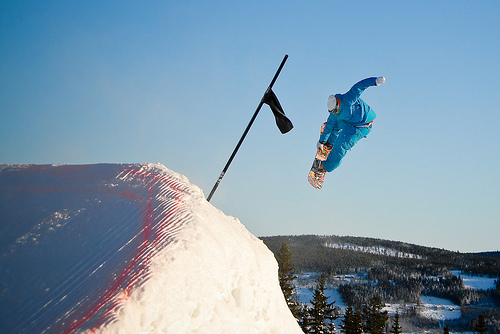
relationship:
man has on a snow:
[303, 70, 385, 189] [197, 226, 223, 253]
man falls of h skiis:
[303, 70, 385, 189] [192, 55, 300, 200]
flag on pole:
[262, 87, 298, 137] [202, 29, 294, 226]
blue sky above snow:
[3, 0, 498, 254] [1, 162, 305, 332]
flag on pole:
[262, 87, 290, 133] [203, 26, 299, 241]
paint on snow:
[16, 167, 181, 332] [1, 162, 305, 332]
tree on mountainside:
[267, 237, 302, 322] [270, 235, 495, 334]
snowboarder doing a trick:
[307, 73, 385, 189] [293, 71, 387, 334]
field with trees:
[4, 154, 323, 332] [258, 235, 499, 332]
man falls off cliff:
[303, 70, 385, 189] [194, 180, 364, 330]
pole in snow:
[203, 45, 303, 222] [1, 162, 305, 332]